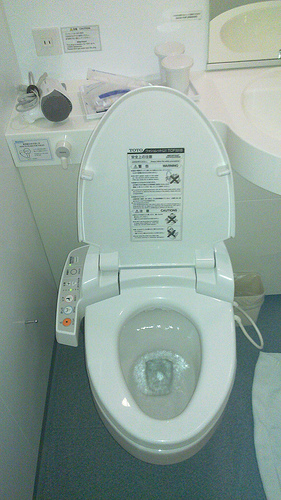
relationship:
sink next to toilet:
[230, 68, 280, 195] [70, 194, 248, 444]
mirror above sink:
[201, 7, 266, 74] [230, 68, 280, 195]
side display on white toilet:
[58, 244, 79, 343] [55, 82, 238, 467]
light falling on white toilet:
[119, 397, 129, 406] [55, 82, 238, 467]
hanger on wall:
[23, 314, 41, 329] [0, 17, 60, 498]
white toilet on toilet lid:
[57, 82, 244, 464] [77, 84, 236, 274]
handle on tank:
[55, 138, 72, 170] [7, 67, 230, 293]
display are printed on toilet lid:
[126, 146, 184, 242] [73, 85, 236, 269]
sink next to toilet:
[230, 65, 280, 194] [48, 87, 240, 465]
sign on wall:
[61, 24, 103, 52] [3, 1, 207, 82]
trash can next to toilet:
[231, 269, 265, 329] [48, 87, 240, 465]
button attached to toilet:
[61, 304, 73, 314] [48, 87, 240, 465]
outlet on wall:
[32, 26, 62, 54] [21, 0, 55, 23]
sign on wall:
[60, 24, 103, 56] [6, 0, 199, 87]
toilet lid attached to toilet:
[50, 81, 248, 275] [48, 87, 240, 465]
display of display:
[126, 146, 184, 242] [126, 146, 184, 242]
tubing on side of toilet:
[232, 301, 266, 351] [48, 87, 240, 465]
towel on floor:
[247, 337, 279, 489] [33, 293, 276, 495]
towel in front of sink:
[247, 337, 279, 489] [5, 72, 279, 203]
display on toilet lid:
[126, 146, 184, 242] [66, 88, 232, 278]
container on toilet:
[162, 49, 194, 97] [53, 107, 277, 309]